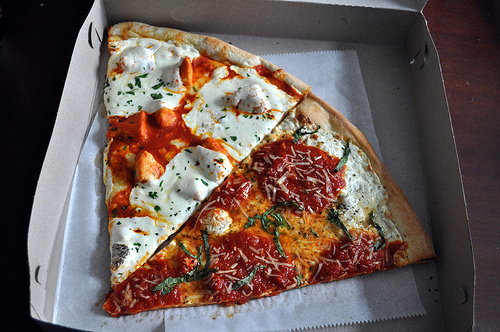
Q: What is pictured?
A: Two slices of pizza.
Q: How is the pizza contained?
A: A pizza box.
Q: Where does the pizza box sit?
A: On a brown table.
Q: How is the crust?
A: Hand tossed.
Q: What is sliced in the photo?
A: The pizza.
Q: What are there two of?
A: Pizza slices.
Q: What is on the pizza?
A: Toppings.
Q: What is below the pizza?
A: White paper.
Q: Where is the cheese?
A: On pizza.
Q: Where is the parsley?
A: On pizza.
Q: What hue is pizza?
A: Red.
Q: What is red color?
A: Pizza.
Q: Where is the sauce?
A: On pizza.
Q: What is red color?
A: Sauce.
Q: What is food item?
A: Pizza.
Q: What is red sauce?
A: Pizza.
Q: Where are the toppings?
A: On slices.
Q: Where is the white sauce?
A: On the pizza.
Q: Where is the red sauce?
A: On the pizza.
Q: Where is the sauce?
A: On the pizza.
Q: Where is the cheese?
A: On the pizza.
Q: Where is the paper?
A: In the box.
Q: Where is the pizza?
A: In the box.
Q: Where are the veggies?
A: On the pizza.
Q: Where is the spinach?
A: On the pizza.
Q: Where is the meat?
A: On the pizza.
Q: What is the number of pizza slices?
A: 2.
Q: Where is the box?
A: On the table.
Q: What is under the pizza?
A: A paper.